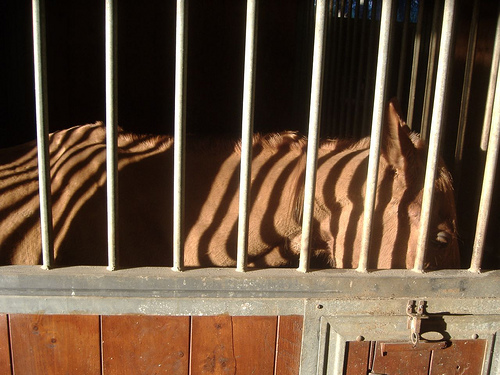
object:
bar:
[411, 0, 455, 270]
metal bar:
[296, 0, 327, 273]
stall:
[0, 0, 497, 375]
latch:
[407, 300, 429, 346]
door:
[319, 316, 499, 374]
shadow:
[366, 164, 398, 270]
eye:
[433, 228, 455, 244]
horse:
[0, 100, 462, 270]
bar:
[173, 1, 188, 270]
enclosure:
[1, 0, 499, 374]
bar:
[29, 0, 55, 268]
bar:
[102, 2, 118, 271]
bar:
[169, 2, 185, 270]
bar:
[235, 0, 255, 272]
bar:
[295, 0, 327, 271]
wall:
[0, 299, 303, 373]